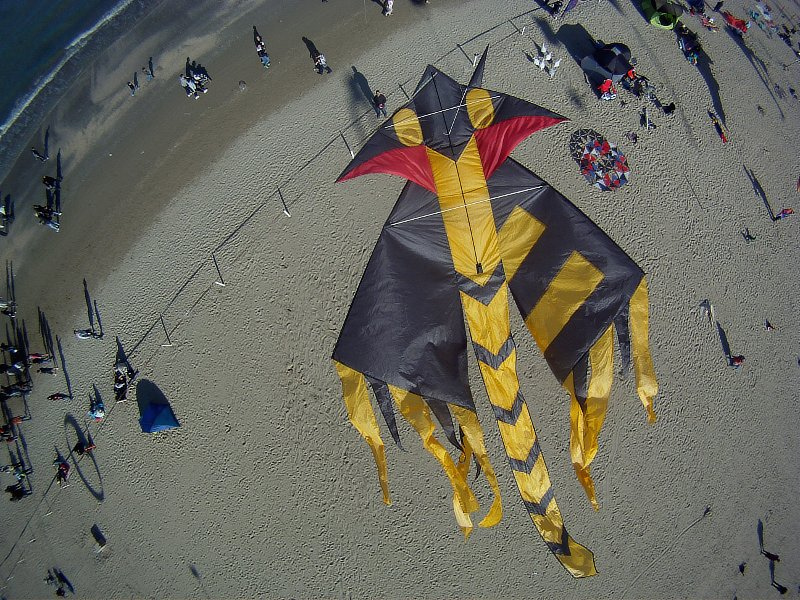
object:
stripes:
[463, 258, 598, 579]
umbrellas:
[567, 127, 632, 191]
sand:
[0, 357, 377, 599]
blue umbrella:
[135, 379, 181, 434]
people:
[0, 273, 142, 502]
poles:
[161, 181, 303, 315]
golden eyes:
[391, 88, 493, 147]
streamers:
[335, 357, 513, 542]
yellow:
[393, 107, 423, 147]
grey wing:
[486, 155, 646, 413]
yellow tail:
[439, 169, 614, 581]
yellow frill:
[564, 366, 664, 510]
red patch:
[335, 116, 566, 196]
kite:
[326, 40, 660, 581]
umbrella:
[591, 42, 633, 78]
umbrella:
[135, 379, 181, 433]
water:
[0, 1, 132, 136]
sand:
[0, 0, 427, 363]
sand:
[1, 3, 800, 600]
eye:
[466, 88, 496, 130]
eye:
[391, 108, 422, 148]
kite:
[567, 127, 629, 193]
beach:
[0, 189, 292, 598]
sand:
[570, 107, 800, 252]